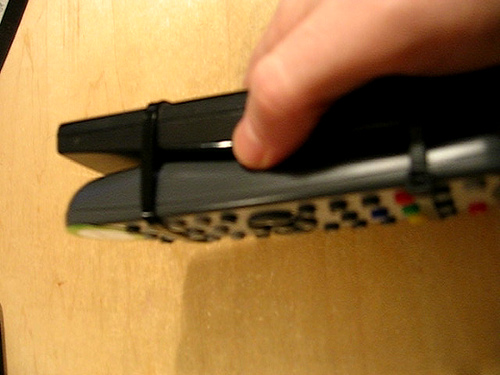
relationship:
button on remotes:
[383, 178, 434, 220] [87, 123, 194, 226]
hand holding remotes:
[302, 4, 456, 57] [87, 123, 194, 226]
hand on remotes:
[302, 4, 456, 57] [87, 123, 194, 226]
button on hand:
[383, 178, 434, 220] [302, 4, 456, 57]